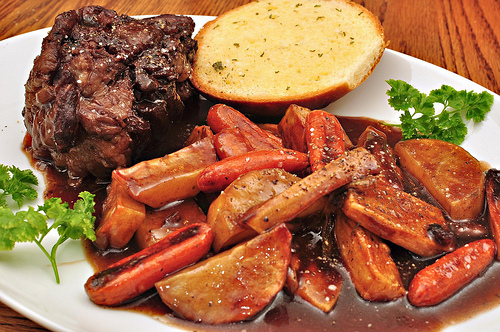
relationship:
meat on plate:
[56, 37, 162, 149] [414, 55, 448, 88]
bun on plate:
[257, 19, 337, 76] [414, 55, 448, 88]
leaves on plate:
[399, 80, 458, 131] [414, 55, 448, 88]